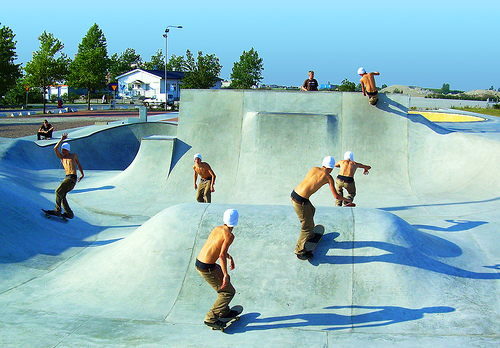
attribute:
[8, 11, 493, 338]
park — skateboard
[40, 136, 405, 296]
men — shirtless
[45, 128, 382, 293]
men — shirtless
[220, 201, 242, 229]
hat — white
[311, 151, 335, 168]
hat — white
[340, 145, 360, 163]
hat — white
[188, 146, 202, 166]
hat — white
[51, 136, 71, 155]
hat — white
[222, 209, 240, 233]
hat — white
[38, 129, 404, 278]
men — shirtless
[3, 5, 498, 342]
picture — digital, enhanced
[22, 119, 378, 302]
men — identical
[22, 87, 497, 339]
course — skateboard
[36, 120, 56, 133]
shirt — black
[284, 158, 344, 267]
skateboarder — shirtless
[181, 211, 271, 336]
skateboarder — shirtless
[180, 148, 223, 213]
skateboarder — shirtless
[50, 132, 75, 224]
skateboarder — shirtless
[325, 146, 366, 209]
skateboarder — shirtless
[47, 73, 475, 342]
skaters — skating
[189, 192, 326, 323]
ramp — blue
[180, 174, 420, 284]
park — grey, concrete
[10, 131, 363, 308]
boys — skating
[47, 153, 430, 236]
caps — white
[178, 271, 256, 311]
pants — green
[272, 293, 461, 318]
shadow — dark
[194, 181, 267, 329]
skater — bent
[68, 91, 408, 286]
track — bumpy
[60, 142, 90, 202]
skater — skating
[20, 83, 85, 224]
skater — skating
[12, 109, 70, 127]
viewer — seated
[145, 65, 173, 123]
pole — thin